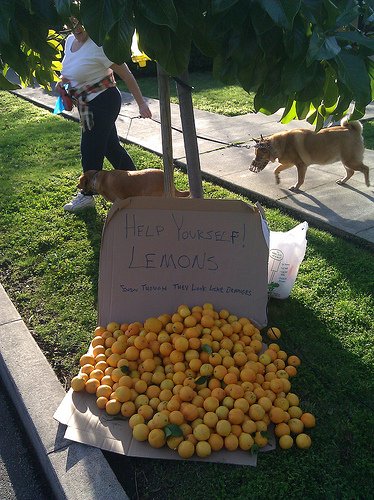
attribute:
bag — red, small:
[50, 82, 69, 113]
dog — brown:
[248, 121, 370, 192]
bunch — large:
[70, 299, 316, 458]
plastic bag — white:
[266, 221, 307, 301]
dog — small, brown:
[69, 155, 189, 203]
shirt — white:
[48, 33, 126, 100]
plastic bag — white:
[267, 222, 305, 297]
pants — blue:
[79, 86, 136, 171]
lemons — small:
[174, 437, 214, 457]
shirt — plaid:
[65, 70, 118, 134]